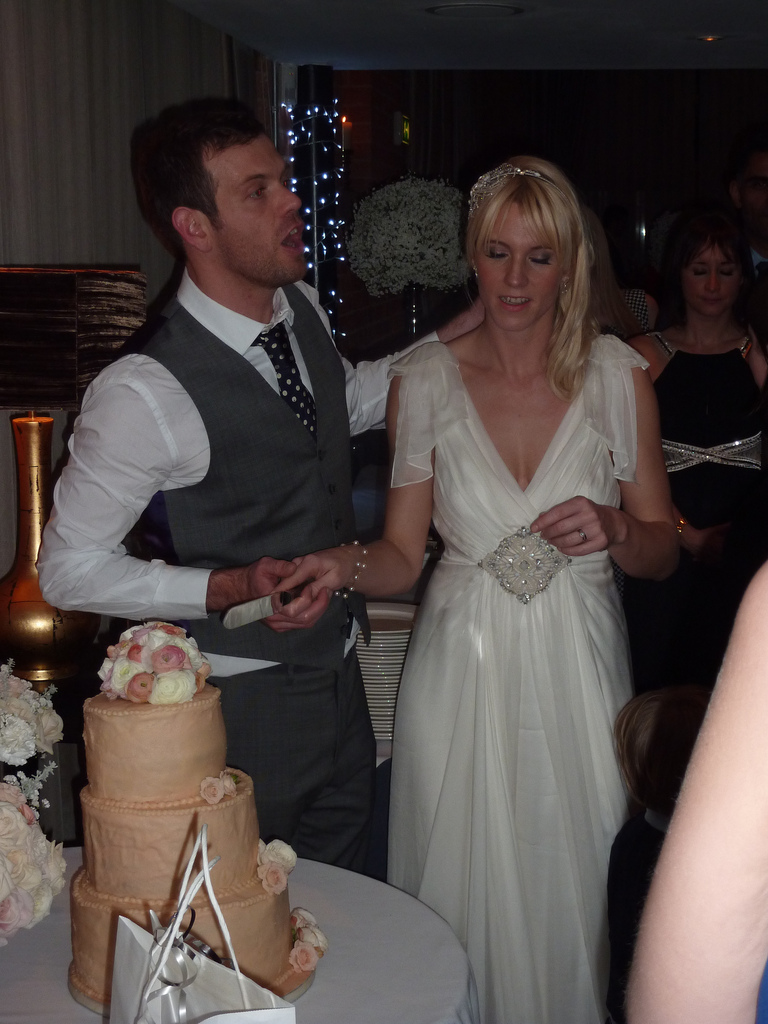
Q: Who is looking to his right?
A: A man.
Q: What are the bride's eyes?
A: Closed.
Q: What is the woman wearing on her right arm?
A: A bracelet.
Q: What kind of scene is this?
A: Indoors.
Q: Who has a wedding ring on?
A: The bride.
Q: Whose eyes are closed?
A: A lady's.